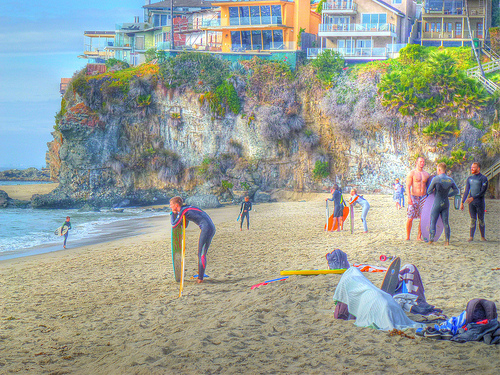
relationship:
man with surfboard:
[144, 197, 211, 268] [169, 204, 184, 281]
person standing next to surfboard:
[324, 184, 346, 234] [325, 206, 350, 232]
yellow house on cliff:
[134, 1, 497, 139] [61, 53, 499, 202]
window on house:
[228, 7, 238, 26] [199, 0, 320, 70]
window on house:
[238, 7, 247, 24] [199, 0, 320, 70]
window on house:
[250, 5, 260, 25] [199, 0, 320, 70]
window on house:
[260, 5, 270, 25] [199, 0, 320, 70]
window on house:
[271, 5, 280, 23] [199, 0, 320, 70]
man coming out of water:
[61, 216, 73, 250] [1, 203, 170, 259]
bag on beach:
[326, 248, 348, 270] [0, 188, 499, 372]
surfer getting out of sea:
[59, 212, 71, 249] [0, 204, 212, 268]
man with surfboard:
[144, 197, 211, 268] [148, 206, 200, 278]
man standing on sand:
[144, 197, 211, 268] [32, 279, 342, 366]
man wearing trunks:
[399, 149, 438, 249] [404, 190, 430, 220]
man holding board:
[416, 160, 486, 255] [418, 189, 450, 248]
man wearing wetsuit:
[334, 259, 498, 351] [468, 178, 489, 237]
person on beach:
[166, 193, 218, 285] [0, 188, 499, 372]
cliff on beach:
[31, 63, 498, 199] [0, 188, 499, 372]